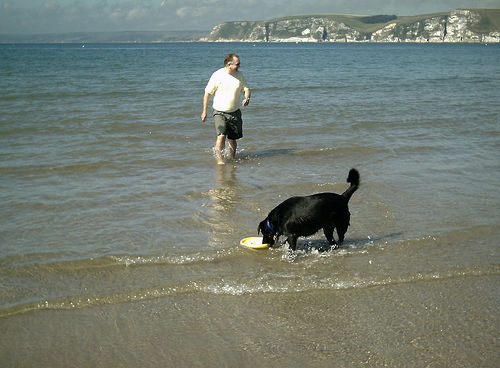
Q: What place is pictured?
A: It is a shore.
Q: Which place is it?
A: It is a shore.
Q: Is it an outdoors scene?
A: Yes, it is outdoors.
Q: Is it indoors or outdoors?
A: It is outdoors.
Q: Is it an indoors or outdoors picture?
A: It is outdoors.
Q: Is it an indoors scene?
A: No, it is outdoors.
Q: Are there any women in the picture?
A: No, there are no women.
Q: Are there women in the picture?
A: No, there are no women.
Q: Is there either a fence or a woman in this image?
A: No, there are no women or fences.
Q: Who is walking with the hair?
A: The man is walking with the hair.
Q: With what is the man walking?
A: The man is walking with hair.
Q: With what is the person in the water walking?
A: The man is walking with hair.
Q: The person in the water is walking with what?
A: The man is walking with hair.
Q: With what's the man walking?
A: The man is walking with hair.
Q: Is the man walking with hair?
A: Yes, the man is walking with hair.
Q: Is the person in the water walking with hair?
A: Yes, the man is walking with hair.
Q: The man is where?
A: The man is in the water.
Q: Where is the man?
A: The man is in the water.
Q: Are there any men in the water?
A: Yes, there is a man in the water.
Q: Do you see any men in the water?
A: Yes, there is a man in the water.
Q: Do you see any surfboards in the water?
A: No, there is a man in the water.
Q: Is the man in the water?
A: Yes, the man is in the water.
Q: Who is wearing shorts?
A: The man is wearing shorts.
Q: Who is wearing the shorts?
A: The man is wearing shorts.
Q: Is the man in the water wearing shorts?
A: Yes, the man is wearing shorts.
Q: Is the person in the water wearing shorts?
A: Yes, the man is wearing shorts.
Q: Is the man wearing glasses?
A: No, the man is wearing shorts.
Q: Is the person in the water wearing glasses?
A: No, the man is wearing shorts.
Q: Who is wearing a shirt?
A: The man is wearing a shirt.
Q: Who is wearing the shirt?
A: The man is wearing a shirt.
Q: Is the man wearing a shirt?
A: Yes, the man is wearing a shirt.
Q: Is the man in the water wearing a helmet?
A: No, the man is wearing a shirt.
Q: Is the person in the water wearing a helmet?
A: No, the man is wearing a shirt.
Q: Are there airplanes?
A: No, there are no airplanes.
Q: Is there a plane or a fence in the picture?
A: No, there are no airplanes or fences.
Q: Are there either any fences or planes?
A: No, there are no planes or fences.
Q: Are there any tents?
A: No, there are no tents.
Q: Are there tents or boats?
A: No, there are no tents or boats.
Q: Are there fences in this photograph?
A: No, there are no fences.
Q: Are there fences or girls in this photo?
A: No, there are no fences or girls.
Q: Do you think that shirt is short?
A: Yes, the shirt is short.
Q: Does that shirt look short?
A: Yes, the shirt is short.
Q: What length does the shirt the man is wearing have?
A: The shirt has short length.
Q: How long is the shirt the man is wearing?
A: The shirt is short.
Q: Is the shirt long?
A: No, the shirt is short.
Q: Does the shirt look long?
A: No, the shirt is short.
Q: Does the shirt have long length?
A: No, the shirt is short.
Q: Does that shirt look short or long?
A: The shirt is short.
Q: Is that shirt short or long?
A: The shirt is short.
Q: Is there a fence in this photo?
A: No, there are no fences.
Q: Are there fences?
A: No, there are no fences.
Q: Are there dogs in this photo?
A: Yes, there is a dog.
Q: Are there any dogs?
A: Yes, there is a dog.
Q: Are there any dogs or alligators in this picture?
A: Yes, there is a dog.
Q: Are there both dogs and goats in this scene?
A: No, there is a dog but no goats.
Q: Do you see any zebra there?
A: No, there are no zebras.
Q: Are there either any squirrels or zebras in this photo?
A: No, there are no zebras or squirrels.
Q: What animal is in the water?
A: The animal is a dog.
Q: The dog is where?
A: The dog is in the water.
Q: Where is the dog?
A: The dog is in the water.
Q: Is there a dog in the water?
A: Yes, there is a dog in the water.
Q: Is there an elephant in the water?
A: No, there is a dog in the water.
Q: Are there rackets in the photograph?
A: No, there are no rackets.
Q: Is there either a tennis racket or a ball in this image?
A: No, there are no rackets or balls.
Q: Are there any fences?
A: No, there are no fences.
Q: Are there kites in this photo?
A: No, there are no kites.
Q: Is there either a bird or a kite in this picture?
A: No, there are no kites or birds.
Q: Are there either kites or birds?
A: No, there are no kites or birds.